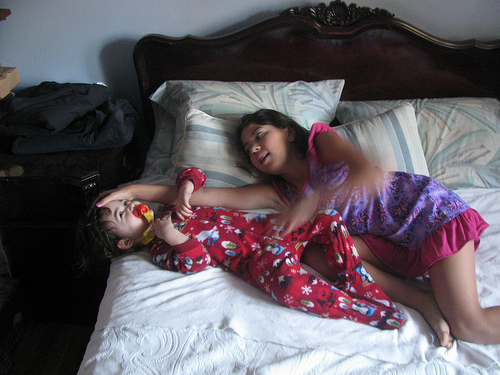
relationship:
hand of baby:
[148, 207, 178, 239] [88, 167, 413, 335]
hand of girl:
[276, 190, 317, 231] [88, 107, 498, 354]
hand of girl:
[92, 183, 140, 207] [88, 107, 498, 354]